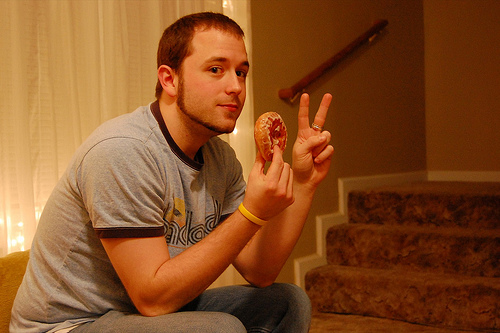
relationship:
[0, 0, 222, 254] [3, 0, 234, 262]
curtains over window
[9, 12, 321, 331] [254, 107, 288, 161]
man holding donut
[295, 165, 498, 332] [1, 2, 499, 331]
stairs in background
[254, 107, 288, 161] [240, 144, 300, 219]
donut in hand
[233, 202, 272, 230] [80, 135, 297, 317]
wristband on arm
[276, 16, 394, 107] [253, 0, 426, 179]
railing on wall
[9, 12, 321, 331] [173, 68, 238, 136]
man has facial hair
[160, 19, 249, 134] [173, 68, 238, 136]
man's face has facial hair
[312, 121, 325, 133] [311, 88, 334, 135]
ring on finger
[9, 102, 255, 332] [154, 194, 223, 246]
t-shirt has design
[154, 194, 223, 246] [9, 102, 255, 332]
design on t-shirt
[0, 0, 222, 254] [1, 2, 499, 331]
curtains in background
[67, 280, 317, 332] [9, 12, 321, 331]
denim on man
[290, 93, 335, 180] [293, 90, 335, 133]
hand in peace sign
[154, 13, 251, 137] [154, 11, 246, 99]
head has hair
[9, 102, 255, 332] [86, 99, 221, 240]
shirt has dark blue edges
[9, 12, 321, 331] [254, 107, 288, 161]
man eating donut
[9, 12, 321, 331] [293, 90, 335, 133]
man giving peace sign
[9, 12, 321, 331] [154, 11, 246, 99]
man has hair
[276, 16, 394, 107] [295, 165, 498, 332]
handrail beside stairs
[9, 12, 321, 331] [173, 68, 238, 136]
guy has beard